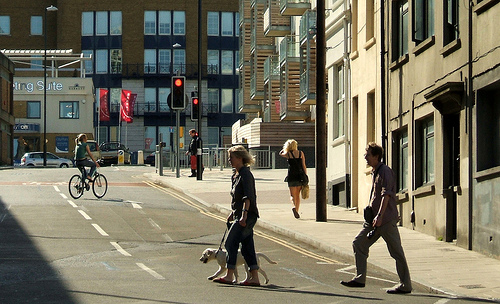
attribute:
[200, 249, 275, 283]
dog — haired, white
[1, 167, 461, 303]
street — tar covered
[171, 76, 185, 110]
light — red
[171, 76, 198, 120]
stoplights — red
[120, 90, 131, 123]
flag — red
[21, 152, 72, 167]
car — silver, parked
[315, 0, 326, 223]
pole — brown